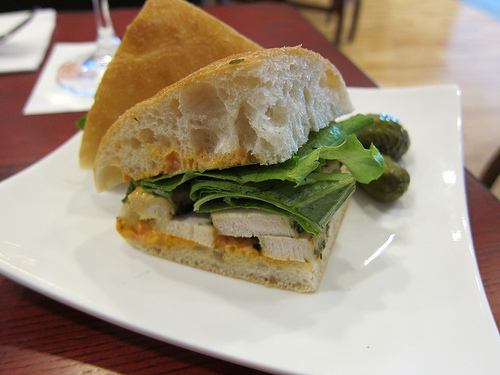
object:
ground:
[367, 10, 481, 76]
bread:
[118, 201, 357, 295]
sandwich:
[89, 47, 388, 295]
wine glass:
[54, 0, 127, 101]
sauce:
[117, 216, 186, 248]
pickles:
[356, 154, 410, 202]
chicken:
[165, 220, 218, 246]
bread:
[96, 44, 350, 200]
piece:
[95, 51, 355, 192]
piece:
[119, 199, 345, 290]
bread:
[78, 0, 294, 167]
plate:
[0, 83, 500, 375]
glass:
[56, 0, 123, 97]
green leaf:
[214, 169, 359, 233]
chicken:
[129, 191, 184, 224]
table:
[0, 1, 499, 373]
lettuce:
[313, 113, 386, 186]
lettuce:
[138, 168, 249, 193]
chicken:
[215, 210, 297, 237]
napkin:
[20, 44, 103, 114]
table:
[142, 76, 269, 149]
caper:
[367, 111, 410, 162]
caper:
[354, 142, 385, 183]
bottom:
[58, 47, 124, 99]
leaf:
[302, 115, 373, 147]